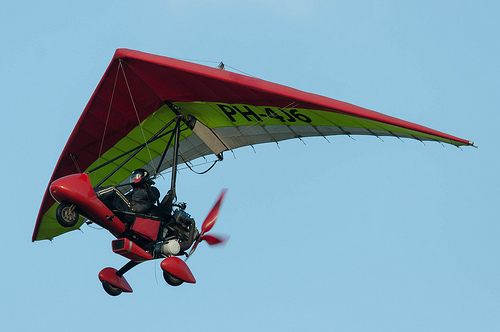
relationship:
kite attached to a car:
[31, 48, 477, 241] [50, 173, 228, 295]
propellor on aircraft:
[178, 181, 231, 268] [30, 49, 478, 296]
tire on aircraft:
[48, 191, 82, 229] [30, 49, 478, 296]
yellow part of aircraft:
[191, 101, 221, 123] [30, 49, 478, 296]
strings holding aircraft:
[115, 56, 157, 176] [30, 49, 478, 296]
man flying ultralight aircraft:
[124, 165, 161, 219] [30, 49, 478, 296]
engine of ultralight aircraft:
[164, 203, 197, 254] [30, 49, 478, 296]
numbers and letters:
[261, 98, 314, 125] [217, 94, 319, 132]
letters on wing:
[217, 94, 319, 132] [30, 46, 481, 245]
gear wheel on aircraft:
[98, 266, 133, 295] [30, 49, 478, 296]